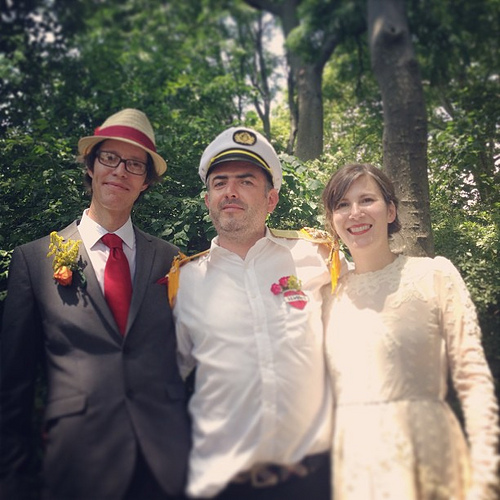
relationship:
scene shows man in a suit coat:
[4, 9, 500, 500] [9, 109, 187, 497]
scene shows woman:
[4, 9, 500, 500] [321, 165, 497, 500]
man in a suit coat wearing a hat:
[9, 109, 187, 497] [76, 104, 177, 173]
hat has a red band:
[76, 104, 177, 173] [92, 127, 161, 148]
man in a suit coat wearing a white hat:
[9, 109, 187, 497] [76, 104, 177, 173]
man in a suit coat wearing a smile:
[9, 109, 187, 497] [98, 178, 131, 196]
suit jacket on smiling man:
[4, 225, 182, 493] [9, 109, 187, 497]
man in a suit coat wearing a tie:
[9, 109, 187, 497] [103, 237, 128, 326]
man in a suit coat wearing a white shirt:
[9, 109, 187, 497] [82, 221, 135, 333]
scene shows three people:
[4, 9, 500, 500] [0, 109, 499, 496]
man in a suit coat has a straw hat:
[9, 109, 187, 497] [76, 104, 177, 173]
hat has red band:
[76, 104, 177, 173] [92, 127, 161, 148]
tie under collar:
[103, 237, 128, 326] [82, 216, 135, 250]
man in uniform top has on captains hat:
[180, 125, 335, 467] [196, 127, 291, 194]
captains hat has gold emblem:
[196, 127, 291, 194] [234, 133, 256, 148]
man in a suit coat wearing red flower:
[9, 109, 187, 497] [52, 265, 73, 288]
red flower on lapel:
[52, 265, 73, 288] [56, 225, 115, 344]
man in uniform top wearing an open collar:
[180, 125, 335, 467] [211, 237, 278, 258]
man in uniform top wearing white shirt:
[180, 125, 335, 467] [179, 232, 329, 478]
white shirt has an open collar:
[179, 232, 329, 478] [211, 237, 278, 258]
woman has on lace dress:
[321, 165, 497, 500] [327, 260, 499, 495]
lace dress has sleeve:
[327, 260, 499, 495] [435, 254, 499, 497]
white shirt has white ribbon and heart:
[82, 221, 135, 333] [288, 284, 311, 312]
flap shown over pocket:
[45, 399, 91, 424] [46, 403, 89, 450]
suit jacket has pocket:
[4, 225, 182, 493] [46, 403, 89, 450]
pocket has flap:
[46, 403, 89, 450] [45, 399, 91, 424]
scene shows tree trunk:
[4, 9, 500, 500] [373, 1, 430, 257]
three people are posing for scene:
[0, 109, 499, 496] [4, 9, 500, 500]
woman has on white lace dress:
[321, 165, 497, 500] [327, 260, 499, 495]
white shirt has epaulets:
[179, 232, 329, 478] [183, 229, 331, 265]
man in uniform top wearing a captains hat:
[180, 125, 335, 467] [196, 127, 291, 194]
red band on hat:
[92, 127, 161, 148] [76, 104, 177, 173]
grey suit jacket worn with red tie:
[4, 225, 182, 493] [103, 237, 128, 326]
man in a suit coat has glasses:
[9, 109, 187, 497] [98, 150, 148, 179]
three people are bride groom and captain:
[0, 109, 499, 496] [180, 125, 335, 467]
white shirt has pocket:
[179, 232, 329, 478] [275, 282, 315, 320]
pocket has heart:
[275, 282, 315, 320] [288, 284, 311, 312]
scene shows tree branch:
[4, 9, 500, 500] [250, 1, 308, 42]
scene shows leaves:
[4, 9, 500, 500] [81, 0, 259, 105]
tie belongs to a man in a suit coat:
[103, 237, 128, 326] [9, 109, 187, 497]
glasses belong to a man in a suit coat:
[98, 150, 148, 179] [9, 109, 187, 497]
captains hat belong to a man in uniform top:
[196, 127, 291, 194] [180, 125, 335, 467]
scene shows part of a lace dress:
[4, 9, 500, 500] [327, 260, 499, 495]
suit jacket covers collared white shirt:
[4, 225, 182, 493] [82, 221, 135, 333]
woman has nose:
[321, 165, 497, 500] [347, 207, 368, 228]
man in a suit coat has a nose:
[9, 109, 187, 497] [113, 165, 127, 181]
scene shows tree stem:
[4, 9, 500, 500] [238, 76, 266, 118]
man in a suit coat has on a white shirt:
[9, 109, 187, 497] [82, 221, 135, 333]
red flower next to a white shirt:
[52, 265, 73, 288] [82, 221, 135, 333]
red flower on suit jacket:
[52, 265, 73, 288] [4, 225, 182, 493]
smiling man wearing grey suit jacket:
[9, 109, 187, 497] [4, 225, 182, 493]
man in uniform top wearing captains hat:
[180, 125, 335, 467] [196, 127, 291, 194]